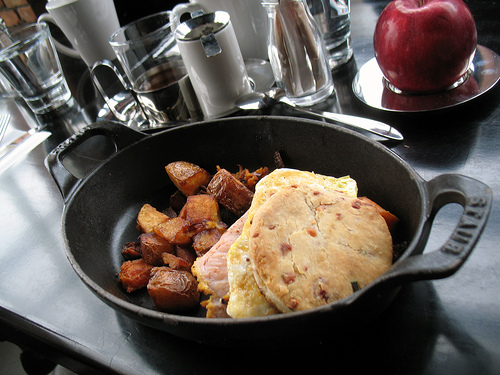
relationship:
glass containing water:
[1, 21, 78, 124] [1, 30, 71, 115]